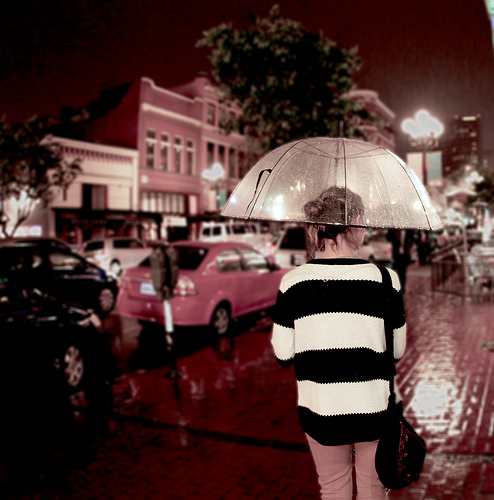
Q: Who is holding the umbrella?
A: Young Woman.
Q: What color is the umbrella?
A: See through.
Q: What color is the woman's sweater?
A: Black and white.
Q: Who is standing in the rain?
A: A woman.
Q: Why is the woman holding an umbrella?
A: It is raining.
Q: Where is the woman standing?
A: On a sidewalk.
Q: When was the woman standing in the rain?
A: During evening hours.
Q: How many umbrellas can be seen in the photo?
A: One.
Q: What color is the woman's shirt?
A: Black and white.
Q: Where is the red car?
A: Parked along the street.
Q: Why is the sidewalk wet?
A: It is raining.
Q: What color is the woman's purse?
A: Black.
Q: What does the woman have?
A: Umbrella.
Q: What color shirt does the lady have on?
A: Black and white.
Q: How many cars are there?
A: More than three.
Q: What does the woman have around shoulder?
A: A purse.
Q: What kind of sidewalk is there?
A: Brick.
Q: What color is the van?
A: Black.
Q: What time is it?
A: Night.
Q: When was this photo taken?
A: At night.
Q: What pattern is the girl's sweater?
A: Striped.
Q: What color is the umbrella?
A: Clear.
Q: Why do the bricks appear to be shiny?
A: They are wet.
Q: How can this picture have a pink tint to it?
A: The photographer's decision.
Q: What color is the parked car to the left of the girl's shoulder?
A: Pink.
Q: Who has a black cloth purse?
A: Girl with striped sweater.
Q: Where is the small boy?
A: There is no boy.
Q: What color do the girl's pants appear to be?
A: Pink.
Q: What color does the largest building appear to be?
A: Pink.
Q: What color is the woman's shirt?
A: Black and white.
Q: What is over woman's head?
A: Umbrella.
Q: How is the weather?
A: It's raining.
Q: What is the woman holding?
A: An umbrella.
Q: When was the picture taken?
A: At night.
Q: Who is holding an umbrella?
A: A woman.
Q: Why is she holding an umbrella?
A: Because it's raining.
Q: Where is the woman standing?
A: On a sidewalk.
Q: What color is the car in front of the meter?
A: Pink.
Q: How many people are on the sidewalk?
A: One.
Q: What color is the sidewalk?
A: Red.